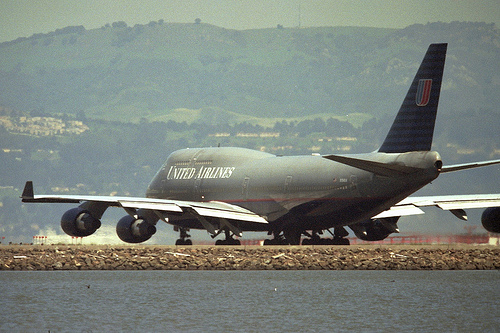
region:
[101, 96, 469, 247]
United Airlines 747 on runway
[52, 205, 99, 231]
Large 747 engine under wing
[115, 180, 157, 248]
Large 747 engine under wing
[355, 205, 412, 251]
Large 747 engine under wing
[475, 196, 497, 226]
Large 747 engine under wing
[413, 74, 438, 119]
united airlines logo on tail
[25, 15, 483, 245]
Tree covered mountain in background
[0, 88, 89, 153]
Small towns on mountains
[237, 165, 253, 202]
Emergency door over wing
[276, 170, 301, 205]
Emergency door over wing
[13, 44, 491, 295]
airplane ready for takeoff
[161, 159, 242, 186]
united airlines written on the side of the plane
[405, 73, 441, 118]
airline logo on tail of airplane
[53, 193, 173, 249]
two large engines on left wing of the plane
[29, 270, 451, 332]
body of water in the foreground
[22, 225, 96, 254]
airport runway light indicators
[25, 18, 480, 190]
hills overlooking an airport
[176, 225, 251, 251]
airplane's landing gear down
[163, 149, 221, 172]
second row of seats/passengers on a plane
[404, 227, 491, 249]
orange caution fence on a runway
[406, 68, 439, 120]
Blue and red Sticker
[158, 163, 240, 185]
White lettering on plane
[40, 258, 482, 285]
Shore line with lots of rocks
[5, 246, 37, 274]
Small groups of rock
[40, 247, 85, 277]
Small groups of rock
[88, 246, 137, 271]
Small groups of rock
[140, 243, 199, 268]
Small groups of rock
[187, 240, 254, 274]
Small groups of rock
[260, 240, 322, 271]
Small groups of rock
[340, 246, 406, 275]
Small groups of rock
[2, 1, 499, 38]
clear sky of horizon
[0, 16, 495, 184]
face of mountain with vegetation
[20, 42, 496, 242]
rear view of airplane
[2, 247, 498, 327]
stone wall overlooking rocks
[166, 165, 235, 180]
white words on gray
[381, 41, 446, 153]
logo on plate tail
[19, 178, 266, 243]
two engines under wing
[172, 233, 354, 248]
wheels of landing gear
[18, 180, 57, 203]
upturned tip of wing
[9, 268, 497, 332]
small ripples on water surface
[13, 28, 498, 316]
a plane near a body of water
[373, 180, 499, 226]
right wing of plane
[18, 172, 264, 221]
left wing of plane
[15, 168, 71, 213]
tip of plane's wing is bend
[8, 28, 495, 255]
plane is color gray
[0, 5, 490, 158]
mountains behind a plane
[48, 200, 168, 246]
two plane engines below a wing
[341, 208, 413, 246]
engine below a right wing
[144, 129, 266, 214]
white letters of plane says "United Airlines"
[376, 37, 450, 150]
vertical stabilizer of plane